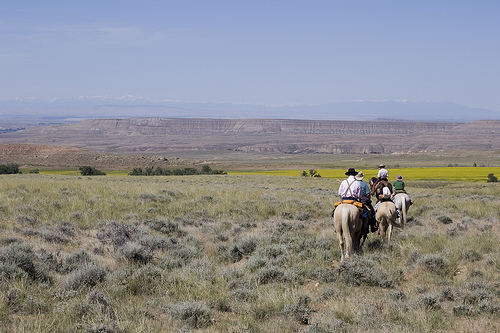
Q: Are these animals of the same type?
A: Yes, all the animals are horses.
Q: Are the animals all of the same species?
A: Yes, all the animals are horses.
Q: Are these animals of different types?
A: No, all the animals are horses.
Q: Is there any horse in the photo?
A: Yes, there is a horse.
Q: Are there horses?
A: Yes, there is a horse.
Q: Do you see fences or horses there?
A: Yes, there is a horse.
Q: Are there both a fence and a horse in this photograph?
A: No, there is a horse but no fences.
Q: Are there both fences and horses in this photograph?
A: No, there is a horse but no fences.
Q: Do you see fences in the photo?
A: No, there are no fences.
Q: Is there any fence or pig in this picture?
A: No, there are no fences or pigs.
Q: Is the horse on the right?
A: Yes, the horse is on the right of the image.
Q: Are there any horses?
A: Yes, there is a horse.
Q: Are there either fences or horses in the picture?
A: Yes, there is a horse.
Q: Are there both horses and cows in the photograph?
A: No, there is a horse but no cows.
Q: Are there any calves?
A: No, there are no calves.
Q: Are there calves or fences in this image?
A: No, there are no calves or fences.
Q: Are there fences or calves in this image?
A: No, there are no calves or fences.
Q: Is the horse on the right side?
A: Yes, the horse is on the right of the image.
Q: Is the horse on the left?
A: No, the horse is on the right of the image.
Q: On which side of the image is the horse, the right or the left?
A: The horse is on the right of the image.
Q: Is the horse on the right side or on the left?
A: The horse is on the right of the image.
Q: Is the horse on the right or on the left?
A: The horse is on the right of the image.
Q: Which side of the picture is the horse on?
A: The horse is on the right of the image.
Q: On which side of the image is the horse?
A: The horse is on the right of the image.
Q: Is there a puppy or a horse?
A: Yes, there is a horse.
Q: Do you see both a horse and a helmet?
A: No, there is a horse but no helmets.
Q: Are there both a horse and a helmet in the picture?
A: No, there is a horse but no helmets.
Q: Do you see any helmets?
A: No, there are no helmets.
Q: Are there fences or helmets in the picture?
A: No, there are no helmets or fences.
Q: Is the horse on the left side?
A: No, the horse is on the right of the image.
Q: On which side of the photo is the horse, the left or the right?
A: The horse is on the right of the image.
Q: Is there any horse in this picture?
A: Yes, there is a horse.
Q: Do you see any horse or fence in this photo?
A: Yes, there is a horse.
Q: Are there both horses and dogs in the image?
A: No, there is a horse but no dogs.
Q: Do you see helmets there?
A: No, there are no helmets.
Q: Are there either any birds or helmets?
A: No, there are no helmets or birds.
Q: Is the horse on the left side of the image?
A: No, the horse is on the right of the image.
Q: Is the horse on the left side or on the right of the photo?
A: The horse is on the right of the image.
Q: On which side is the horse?
A: The horse is on the right of the image.